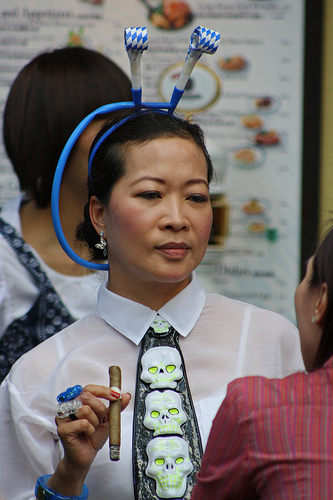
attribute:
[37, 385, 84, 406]
ring — blue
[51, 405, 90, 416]
ring — clear